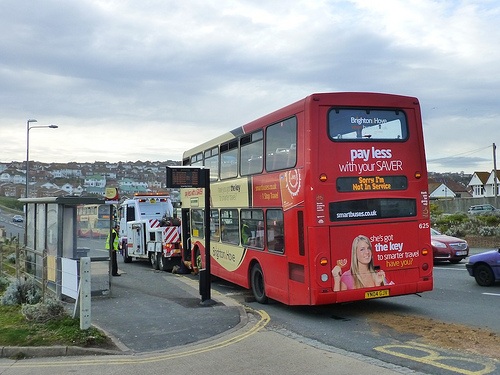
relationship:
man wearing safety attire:
[101, 220, 130, 273] [103, 229, 121, 252]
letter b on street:
[371, 344, 496, 374] [2, 214, 496, 372]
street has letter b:
[2, 214, 496, 372] [371, 344, 496, 374]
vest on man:
[103, 228, 118, 248] [104, 219, 121, 283]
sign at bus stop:
[166, 165, 212, 301] [160, 162, 213, 305]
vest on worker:
[103, 231, 130, 261] [94, 216, 132, 281]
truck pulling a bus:
[110, 189, 188, 271] [170, 87, 435, 312]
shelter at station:
[15, 195, 111, 297] [0, 226, 250, 363]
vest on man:
[96, 229, 124, 260] [105, 221, 120, 276]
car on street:
[430, 225, 472, 265] [2, 214, 496, 372]